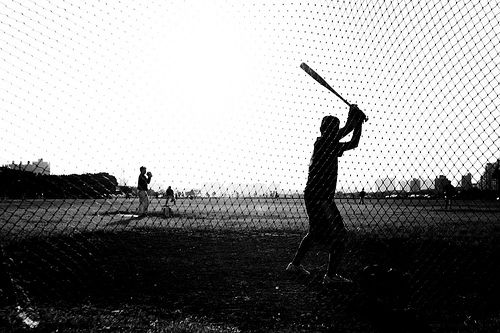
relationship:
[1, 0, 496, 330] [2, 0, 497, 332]
holes in fence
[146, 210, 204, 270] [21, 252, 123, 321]
small holes are in fence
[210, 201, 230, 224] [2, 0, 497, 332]
holes in fence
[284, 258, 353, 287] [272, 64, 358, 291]
shoes on baseball diamond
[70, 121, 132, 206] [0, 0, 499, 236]
holes in fence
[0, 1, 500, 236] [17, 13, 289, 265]
holes in fence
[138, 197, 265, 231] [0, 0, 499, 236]
holes in fence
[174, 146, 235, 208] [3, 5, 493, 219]
holes in fence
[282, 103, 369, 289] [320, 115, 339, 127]
kid on hat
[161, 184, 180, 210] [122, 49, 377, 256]
outfielder on baseball game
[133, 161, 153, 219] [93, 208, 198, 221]
pitcher located on pitchers mound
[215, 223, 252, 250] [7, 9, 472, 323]
holes holding fence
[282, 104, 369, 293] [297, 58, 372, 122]
kid holding baseball bat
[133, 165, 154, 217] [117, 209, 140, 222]
pitcher on diamond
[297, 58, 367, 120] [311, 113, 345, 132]
baseball bat held head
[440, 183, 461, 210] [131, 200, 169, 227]
baseman on base